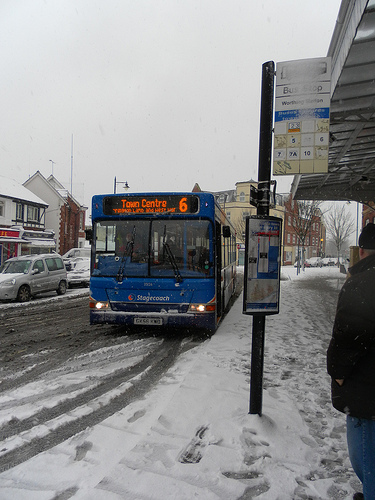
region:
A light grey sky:
[0, 1, 366, 247]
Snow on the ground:
[3, 245, 374, 497]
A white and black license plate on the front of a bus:
[131, 316, 163, 327]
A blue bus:
[88, 191, 239, 339]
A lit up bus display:
[102, 195, 198, 219]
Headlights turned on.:
[89, 299, 211, 314]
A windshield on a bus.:
[95, 218, 210, 279]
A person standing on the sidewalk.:
[320, 218, 373, 498]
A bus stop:
[249, 3, 372, 498]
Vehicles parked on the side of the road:
[3, 221, 108, 305]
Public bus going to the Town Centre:
[91, 192, 238, 330]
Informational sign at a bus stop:
[244, 213, 283, 313]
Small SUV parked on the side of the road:
[1, 251, 69, 300]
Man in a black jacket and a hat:
[326, 222, 374, 498]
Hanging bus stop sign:
[275, 56, 329, 174]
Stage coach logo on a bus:
[132, 292, 172, 304]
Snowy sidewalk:
[83, 267, 362, 496]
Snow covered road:
[0, 285, 207, 498]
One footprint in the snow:
[222, 470, 264, 479]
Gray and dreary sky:
[1, 1, 360, 257]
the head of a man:
[343, 219, 374, 270]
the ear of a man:
[331, 227, 372, 270]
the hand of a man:
[309, 329, 361, 412]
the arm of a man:
[299, 250, 373, 445]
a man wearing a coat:
[339, 219, 371, 267]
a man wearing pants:
[342, 403, 374, 495]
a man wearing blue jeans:
[328, 412, 371, 492]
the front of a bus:
[72, 180, 258, 340]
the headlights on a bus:
[79, 278, 230, 327]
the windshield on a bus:
[68, 198, 237, 327]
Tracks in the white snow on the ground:
[32, 477, 50, 495]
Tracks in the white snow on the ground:
[55, 440, 111, 474]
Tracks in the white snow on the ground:
[93, 419, 128, 450]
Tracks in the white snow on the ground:
[169, 417, 223, 485]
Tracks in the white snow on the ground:
[225, 458, 246, 496]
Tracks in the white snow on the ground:
[305, 442, 339, 481]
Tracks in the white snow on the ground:
[298, 397, 327, 424]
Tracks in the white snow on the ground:
[279, 368, 318, 400]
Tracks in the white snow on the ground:
[225, 352, 248, 371]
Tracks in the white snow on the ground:
[272, 327, 310, 355]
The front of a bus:
[85, 189, 218, 332]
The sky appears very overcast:
[0, 2, 341, 193]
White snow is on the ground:
[1, 255, 361, 498]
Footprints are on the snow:
[2, 287, 365, 499]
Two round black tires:
[13, 275, 71, 308]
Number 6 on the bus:
[174, 191, 191, 216]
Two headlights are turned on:
[90, 295, 208, 315]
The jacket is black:
[319, 251, 372, 427]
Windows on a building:
[10, 197, 46, 229]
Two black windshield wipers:
[114, 232, 186, 288]